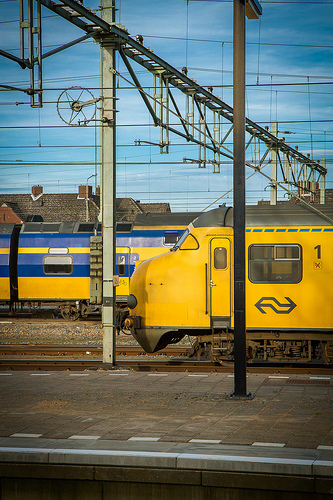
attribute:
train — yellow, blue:
[0, 220, 195, 321]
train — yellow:
[264, 216, 327, 319]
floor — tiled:
[131, 415, 171, 437]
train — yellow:
[110, 233, 331, 333]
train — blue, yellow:
[116, 194, 327, 350]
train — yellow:
[130, 194, 332, 372]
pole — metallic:
[228, 4, 251, 391]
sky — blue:
[4, 0, 327, 194]